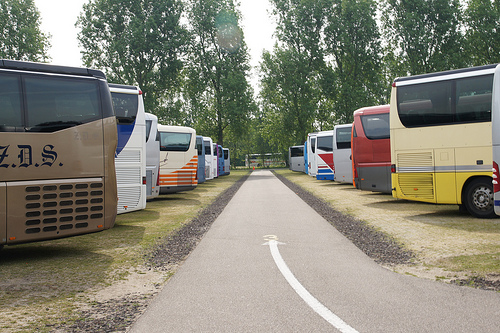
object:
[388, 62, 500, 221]
rv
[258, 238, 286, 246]
white arrow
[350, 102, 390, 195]
vehicle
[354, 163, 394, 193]
fender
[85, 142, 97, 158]
paint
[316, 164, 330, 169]
stripes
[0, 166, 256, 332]
glasses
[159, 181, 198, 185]
orange stripes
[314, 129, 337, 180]
bus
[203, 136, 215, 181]
bus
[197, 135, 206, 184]
bus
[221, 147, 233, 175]
bus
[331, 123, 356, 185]
bus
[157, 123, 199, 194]
bus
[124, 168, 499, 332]
road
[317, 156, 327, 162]
paint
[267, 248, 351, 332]
line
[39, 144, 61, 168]
initials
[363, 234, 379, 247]
rocks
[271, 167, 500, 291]
grass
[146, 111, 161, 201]
bus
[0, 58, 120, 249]
rv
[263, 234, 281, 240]
number three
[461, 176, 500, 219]
tire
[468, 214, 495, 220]
rim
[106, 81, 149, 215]
white rv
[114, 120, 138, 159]
blue stripe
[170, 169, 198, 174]
stripes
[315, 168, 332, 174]
markings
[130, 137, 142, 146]
paint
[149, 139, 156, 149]
paint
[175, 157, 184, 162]
paint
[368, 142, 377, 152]
paint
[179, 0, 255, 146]
trees